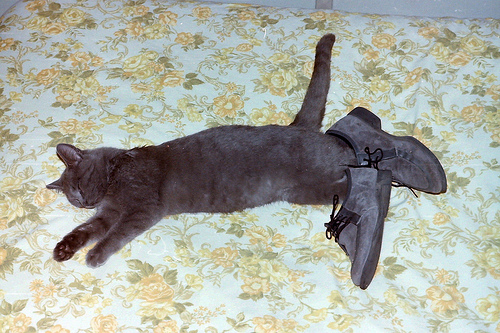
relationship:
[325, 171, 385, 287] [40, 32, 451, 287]
shoe on cat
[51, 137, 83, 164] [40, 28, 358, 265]
ear on cat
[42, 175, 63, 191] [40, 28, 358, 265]
ear on cat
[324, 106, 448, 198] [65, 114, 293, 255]
shoe on cat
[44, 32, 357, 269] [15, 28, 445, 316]
cat on comforter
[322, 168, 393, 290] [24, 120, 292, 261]
shoe on cat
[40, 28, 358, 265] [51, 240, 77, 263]
cat has front paw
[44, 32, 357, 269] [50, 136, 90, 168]
cat has ear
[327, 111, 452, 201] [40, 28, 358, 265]
shoe on cat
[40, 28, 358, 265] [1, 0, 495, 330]
cat on bed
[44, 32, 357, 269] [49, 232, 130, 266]
cat has front paw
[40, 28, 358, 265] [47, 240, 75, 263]
cat has front paw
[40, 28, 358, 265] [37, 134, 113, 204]
cat has head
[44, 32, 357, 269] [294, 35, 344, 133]
cat has tail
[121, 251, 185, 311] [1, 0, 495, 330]
flowers on bed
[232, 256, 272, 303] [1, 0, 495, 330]
flowers on bed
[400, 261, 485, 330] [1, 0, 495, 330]
flowers on bed